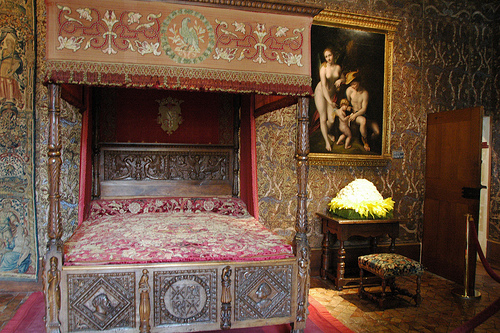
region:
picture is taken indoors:
[19, 44, 373, 319]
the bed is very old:
[25, 36, 407, 272]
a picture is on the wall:
[316, 25, 437, 187]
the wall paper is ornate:
[305, 15, 479, 148]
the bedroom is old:
[35, 37, 386, 331]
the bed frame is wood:
[32, 34, 269, 327]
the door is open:
[458, 118, 499, 175]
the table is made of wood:
[322, 180, 436, 287]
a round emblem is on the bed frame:
[150, 7, 279, 71]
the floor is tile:
[348, 301, 379, 323]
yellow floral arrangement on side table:
[331, 177, 391, 218]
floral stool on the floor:
[356, 252, 423, 307]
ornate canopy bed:
[36, 6, 316, 325]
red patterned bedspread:
[77, 195, 275, 260]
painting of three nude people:
[313, 38, 386, 164]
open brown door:
[418, 107, 495, 279]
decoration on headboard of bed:
[147, 94, 202, 143]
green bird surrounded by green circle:
[149, 10, 220, 61]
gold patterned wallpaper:
[411, 37, 471, 92]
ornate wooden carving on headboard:
[97, 144, 241, 184]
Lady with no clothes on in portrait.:
[306, 52, 346, 164]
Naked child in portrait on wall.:
[338, 89, 360, 214]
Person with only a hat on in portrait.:
[341, 64, 393, 162]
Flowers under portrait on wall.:
[336, 165, 396, 263]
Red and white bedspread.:
[88, 188, 274, 283]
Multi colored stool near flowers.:
[351, 245, 434, 309]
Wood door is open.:
[416, 117, 455, 286]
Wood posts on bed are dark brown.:
[18, 132, 360, 292]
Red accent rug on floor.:
[191, 288, 369, 328]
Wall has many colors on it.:
[8, 125, 61, 251]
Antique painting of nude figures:
[296, 8, 396, 178]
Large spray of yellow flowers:
[317, 165, 412, 249]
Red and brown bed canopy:
[31, 3, 325, 329]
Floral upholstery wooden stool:
[343, 242, 440, 324]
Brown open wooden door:
[411, 101, 498, 266]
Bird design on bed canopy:
[140, 5, 225, 94]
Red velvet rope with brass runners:
[417, 199, 495, 323]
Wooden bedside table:
[307, 199, 407, 297]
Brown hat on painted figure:
[333, 61, 403, 126]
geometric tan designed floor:
[316, 298, 449, 332]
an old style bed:
[39, 8, 305, 331]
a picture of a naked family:
[293, 2, 405, 192]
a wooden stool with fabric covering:
[340, 245, 450, 328]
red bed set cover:
[65, 184, 305, 296]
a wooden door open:
[401, 71, 497, 279]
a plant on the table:
[296, 172, 403, 248]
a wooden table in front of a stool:
[313, 195, 429, 297]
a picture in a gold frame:
[290, 5, 435, 170]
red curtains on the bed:
[57, 84, 118, 221]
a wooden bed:
[30, 17, 338, 322]